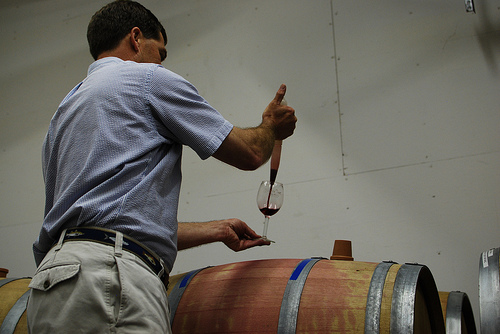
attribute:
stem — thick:
[257, 214, 269, 236]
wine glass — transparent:
[252, 177, 284, 245]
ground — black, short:
[363, 199, 382, 215]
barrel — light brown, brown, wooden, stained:
[164, 254, 448, 331]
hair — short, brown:
[80, 0, 167, 57]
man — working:
[32, 17, 305, 331]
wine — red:
[239, 160, 294, 252]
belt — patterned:
[26, 207, 186, 285]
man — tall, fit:
[73, 32, 282, 237]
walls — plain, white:
[7, 0, 499, 297]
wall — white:
[333, 7, 498, 190]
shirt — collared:
[36, 76, 236, 260]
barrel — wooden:
[165, 238, 445, 331]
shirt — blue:
[29, 57, 233, 267]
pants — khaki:
[22, 224, 170, 332]